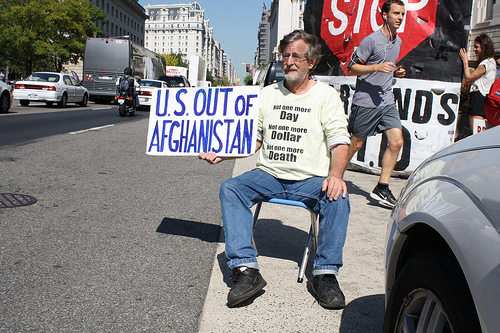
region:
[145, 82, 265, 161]
white protest sign with blue letters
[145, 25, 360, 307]
man sitting on sidewalk holding sign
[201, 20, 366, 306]
man wearing blue jeans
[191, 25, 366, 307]
man wearing cream shirt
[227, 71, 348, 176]
shirt with black lettering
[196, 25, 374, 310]
man with grey hair and beard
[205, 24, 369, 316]
man wearing black shoes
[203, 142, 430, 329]
grey concrete sidewalk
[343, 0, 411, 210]
man running in background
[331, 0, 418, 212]
man running with earphones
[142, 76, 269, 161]
sign with blue letters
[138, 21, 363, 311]
man in chair with sign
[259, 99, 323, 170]
words on man's shirt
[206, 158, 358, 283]
blue jeans on sitting man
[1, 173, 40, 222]
manhole cover in street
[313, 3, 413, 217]
man in shorts jogging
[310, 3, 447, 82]
stop sign on banner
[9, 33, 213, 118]
traffic on city street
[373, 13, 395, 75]
earbuds in jogger's ear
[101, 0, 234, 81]
buildings on city street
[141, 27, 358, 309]
man with sign on busy city street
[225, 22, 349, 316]
man in chair on busy sidewalk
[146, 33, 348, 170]
man holding white sign with blue writing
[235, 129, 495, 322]
front end of vehicle parked on sidewalk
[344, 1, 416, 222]
man in grey t shirt logging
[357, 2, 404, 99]
jogger wearing headphones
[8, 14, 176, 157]
traffic on the street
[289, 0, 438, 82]
image of stop sign with holes in it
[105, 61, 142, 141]
person on motorcycle in traffic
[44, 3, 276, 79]
white buildings on each side of the street in the distance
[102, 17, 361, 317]
a man holding a protest sighn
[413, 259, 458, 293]
black rubber on a tire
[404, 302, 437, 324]
metal center of a tire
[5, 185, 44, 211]
a manhole cover in the street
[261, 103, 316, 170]
a logo on a t-shirt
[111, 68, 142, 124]
a man driving a motorcycle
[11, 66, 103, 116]
a white car following a bus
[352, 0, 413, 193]
a man jogging on a busy street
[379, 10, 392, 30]
earphones in an ear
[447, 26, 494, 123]
a woman taking a photo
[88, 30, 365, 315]
protester seated at curb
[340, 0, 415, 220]
man jogging in front of sign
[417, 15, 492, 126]
woman holding large sign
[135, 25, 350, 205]
man with sign giving his opinion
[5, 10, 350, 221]
traffic driving by protesters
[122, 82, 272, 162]
blue and white sign in capital letters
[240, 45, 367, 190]
message on white shirt with black print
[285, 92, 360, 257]
hand resting on knee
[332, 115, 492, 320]
car parked on sidewalk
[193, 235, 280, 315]
foot leaning to one side